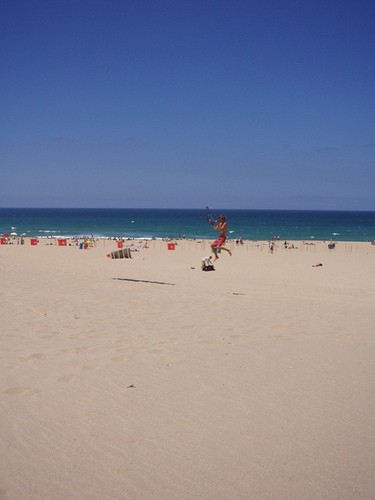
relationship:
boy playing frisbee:
[208, 214, 231, 263] [200, 205, 216, 258]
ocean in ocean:
[0, 206, 374, 242] [4, 188, 366, 247]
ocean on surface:
[0, 206, 374, 242] [116, 210, 209, 224]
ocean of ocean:
[0, 206, 374, 242] [81, 205, 313, 237]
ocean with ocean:
[81, 205, 313, 237] [0, 206, 374, 242]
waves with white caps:
[102, 196, 190, 226] [44, 220, 159, 241]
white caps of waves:
[44, 220, 159, 241] [102, 196, 190, 226]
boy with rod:
[208, 214, 231, 263] [202, 203, 215, 223]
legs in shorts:
[209, 250, 233, 252] [206, 238, 230, 261]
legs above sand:
[212, 240, 235, 262] [179, 242, 321, 350]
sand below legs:
[179, 242, 321, 350] [212, 240, 235, 262]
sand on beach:
[3, 235, 374, 498] [0, 206, 374, 497]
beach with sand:
[0, 206, 374, 497] [3, 235, 374, 498]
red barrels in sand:
[3, 222, 193, 254] [108, 339, 251, 462]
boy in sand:
[208, 214, 231, 263] [61, 324, 157, 416]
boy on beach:
[208, 214, 231, 263] [145, 389, 268, 500]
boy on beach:
[208, 214, 231, 263] [77, 319, 285, 420]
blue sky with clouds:
[0, 0, 375, 214] [39, 37, 306, 156]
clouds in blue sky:
[39, 37, 306, 156] [0, 0, 375, 214]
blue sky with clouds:
[0, 0, 375, 214] [0, 0, 375, 214]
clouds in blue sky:
[0, 0, 375, 214] [0, 0, 375, 214]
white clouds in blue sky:
[197, 182, 240, 194] [74, 34, 319, 134]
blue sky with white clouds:
[74, 34, 319, 134] [197, 182, 240, 194]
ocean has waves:
[0, 206, 374, 242] [5, 229, 178, 241]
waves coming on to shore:
[5, 229, 178, 241] [0, 233, 372, 258]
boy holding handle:
[210, 214, 236, 252] [203, 203, 216, 222]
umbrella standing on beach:
[9, 231, 19, 237] [0, 235, 372, 499]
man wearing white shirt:
[196, 255, 212, 272] [203, 255, 210, 262]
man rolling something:
[196, 255, 212, 272] [204, 264, 215, 270]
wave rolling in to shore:
[233, 223, 313, 240] [3, 236, 374, 268]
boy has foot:
[208, 214, 231, 263] [228, 248, 233, 256]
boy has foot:
[208, 214, 231, 263] [213, 255, 218, 261]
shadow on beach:
[112, 274, 173, 285] [0, 235, 372, 499]